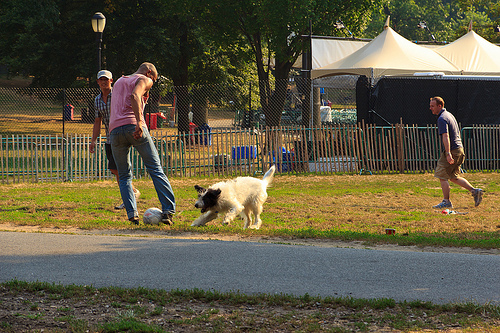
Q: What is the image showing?
A: It is showing a park.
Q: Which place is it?
A: It is a park.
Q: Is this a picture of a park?
A: Yes, it is showing a park.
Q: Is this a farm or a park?
A: It is a park.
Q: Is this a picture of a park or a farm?
A: It is showing a park.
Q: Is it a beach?
A: No, it is a park.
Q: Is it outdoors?
A: Yes, it is outdoors.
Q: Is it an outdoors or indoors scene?
A: It is outdoors.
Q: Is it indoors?
A: No, it is outdoors.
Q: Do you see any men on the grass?
A: Yes, there is a man on the grass.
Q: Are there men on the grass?
A: Yes, there is a man on the grass.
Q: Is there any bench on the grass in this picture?
A: No, there is a man on the grass.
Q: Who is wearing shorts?
A: The man is wearing shorts.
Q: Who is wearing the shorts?
A: The man is wearing shorts.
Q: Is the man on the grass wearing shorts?
A: Yes, the man is wearing shorts.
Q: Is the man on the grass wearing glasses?
A: No, the man is wearing shorts.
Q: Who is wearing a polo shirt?
A: The man is wearing a polo shirt.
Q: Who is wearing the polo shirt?
A: The man is wearing a polo shirt.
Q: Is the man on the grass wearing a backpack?
A: No, the man is wearing a polo shirt.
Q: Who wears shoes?
A: The man wears shoes.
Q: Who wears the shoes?
A: The man wears shoes.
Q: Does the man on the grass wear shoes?
A: Yes, the man wears shoes.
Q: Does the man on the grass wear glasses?
A: No, the man wears shoes.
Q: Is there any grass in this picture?
A: Yes, there is grass.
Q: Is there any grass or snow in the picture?
A: Yes, there is grass.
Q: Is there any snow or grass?
A: Yes, there is grass.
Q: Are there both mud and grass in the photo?
A: No, there is grass but no mud.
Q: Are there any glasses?
A: No, there are no glasses.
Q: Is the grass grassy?
A: Yes, the grass is grassy.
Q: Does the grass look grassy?
A: Yes, the grass is grassy.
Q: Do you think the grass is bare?
A: No, the grass is grassy.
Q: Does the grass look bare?
A: No, the grass is grassy.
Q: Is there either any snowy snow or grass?
A: No, there is grass but it is grassy.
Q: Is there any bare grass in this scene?
A: No, there is grass but it is grassy.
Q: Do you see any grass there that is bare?
A: No, there is grass but it is grassy.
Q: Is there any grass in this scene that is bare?
A: No, there is grass but it is grassy.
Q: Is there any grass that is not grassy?
A: No, there is grass but it is grassy.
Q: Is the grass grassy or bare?
A: The grass is grassy.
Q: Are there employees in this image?
A: No, there are no employees.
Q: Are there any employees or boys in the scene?
A: No, there are no employees or boys.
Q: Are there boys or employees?
A: No, there are no employees or boys.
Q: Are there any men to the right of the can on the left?
A: Yes, there is a man to the right of the can.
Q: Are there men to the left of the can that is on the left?
A: No, the man is to the right of the can.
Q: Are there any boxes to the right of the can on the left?
A: No, there is a man to the right of the can.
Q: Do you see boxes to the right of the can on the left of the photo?
A: No, there is a man to the right of the can.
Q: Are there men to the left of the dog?
A: Yes, there is a man to the left of the dog.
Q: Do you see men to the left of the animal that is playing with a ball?
A: Yes, there is a man to the left of the dog.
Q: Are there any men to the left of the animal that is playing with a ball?
A: Yes, there is a man to the left of the dog.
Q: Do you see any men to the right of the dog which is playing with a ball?
A: No, the man is to the left of the dog.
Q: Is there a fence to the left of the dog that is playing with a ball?
A: No, there is a man to the left of the dog.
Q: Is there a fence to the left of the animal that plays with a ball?
A: No, there is a man to the left of the dog.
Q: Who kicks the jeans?
A: The man kicks the jeans.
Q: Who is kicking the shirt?
A: The man is kicking the shirt.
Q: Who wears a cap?
A: The man wears a cap.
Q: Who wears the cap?
A: The man wears a cap.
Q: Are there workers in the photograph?
A: No, there are no workers.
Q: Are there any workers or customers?
A: No, there are no workers or customers.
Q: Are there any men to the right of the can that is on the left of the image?
A: Yes, there is a man to the right of the can.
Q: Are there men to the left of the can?
A: No, the man is to the right of the can.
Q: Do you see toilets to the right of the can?
A: No, there is a man to the right of the can.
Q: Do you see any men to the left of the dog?
A: Yes, there is a man to the left of the dog.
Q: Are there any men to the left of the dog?
A: Yes, there is a man to the left of the dog.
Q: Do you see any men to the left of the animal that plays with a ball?
A: Yes, there is a man to the left of the dog.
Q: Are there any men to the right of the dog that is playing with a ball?
A: No, the man is to the left of the dog.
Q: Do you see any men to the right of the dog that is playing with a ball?
A: No, the man is to the left of the dog.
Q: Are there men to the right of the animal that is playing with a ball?
A: No, the man is to the left of the dog.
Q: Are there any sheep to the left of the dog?
A: No, there is a man to the left of the dog.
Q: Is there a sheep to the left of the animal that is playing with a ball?
A: No, there is a man to the left of the dog.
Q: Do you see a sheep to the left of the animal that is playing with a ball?
A: No, there is a man to the left of the dog.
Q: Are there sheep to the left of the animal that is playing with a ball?
A: No, there is a man to the left of the dog.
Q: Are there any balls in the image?
A: Yes, there is a ball.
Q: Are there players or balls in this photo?
A: Yes, there is a ball.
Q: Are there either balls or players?
A: Yes, there is a ball.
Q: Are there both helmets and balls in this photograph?
A: No, there is a ball but no helmets.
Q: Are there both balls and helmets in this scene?
A: No, there is a ball but no helmets.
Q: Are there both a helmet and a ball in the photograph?
A: No, there is a ball but no helmets.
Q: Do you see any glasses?
A: No, there are no glasses.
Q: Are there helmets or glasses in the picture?
A: No, there are no glasses or helmets.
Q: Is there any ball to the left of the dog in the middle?
A: Yes, there is a ball to the left of the dog.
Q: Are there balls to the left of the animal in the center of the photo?
A: Yes, there is a ball to the left of the dog.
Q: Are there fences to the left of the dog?
A: No, there is a ball to the left of the dog.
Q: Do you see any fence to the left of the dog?
A: No, there is a ball to the left of the dog.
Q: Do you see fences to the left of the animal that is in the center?
A: No, there is a ball to the left of the dog.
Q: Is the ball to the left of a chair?
A: No, the ball is to the left of a dog.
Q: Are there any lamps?
A: Yes, there is a lamp.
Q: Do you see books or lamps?
A: Yes, there is a lamp.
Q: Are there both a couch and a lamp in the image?
A: No, there is a lamp but no couches.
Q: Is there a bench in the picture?
A: No, there are no benches.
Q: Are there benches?
A: No, there are no benches.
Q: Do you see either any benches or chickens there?
A: No, there are no benches or chickens.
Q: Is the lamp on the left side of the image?
A: Yes, the lamp is on the left of the image.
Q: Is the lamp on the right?
A: No, the lamp is on the left of the image.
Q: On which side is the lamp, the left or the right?
A: The lamp is on the left of the image.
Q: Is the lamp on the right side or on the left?
A: The lamp is on the left of the image.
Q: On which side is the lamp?
A: The lamp is on the left of the image.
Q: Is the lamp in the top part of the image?
A: Yes, the lamp is in the top of the image.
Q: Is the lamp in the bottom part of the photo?
A: No, the lamp is in the top of the image.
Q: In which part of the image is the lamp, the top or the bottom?
A: The lamp is in the top of the image.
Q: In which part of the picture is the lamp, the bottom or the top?
A: The lamp is in the top of the image.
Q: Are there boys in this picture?
A: No, there are no boys.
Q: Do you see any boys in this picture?
A: No, there are no boys.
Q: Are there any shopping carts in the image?
A: No, there are no shopping carts.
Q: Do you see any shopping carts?
A: No, there are no shopping carts.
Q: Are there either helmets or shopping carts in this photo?
A: No, there are no shopping carts or helmets.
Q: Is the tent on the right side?
A: Yes, the tent is on the right of the image.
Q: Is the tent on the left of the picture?
A: No, the tent is on the right of the image.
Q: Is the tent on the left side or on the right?
A: The tent is on the right of the image.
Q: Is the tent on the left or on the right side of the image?
A: The tent is on the right of the image.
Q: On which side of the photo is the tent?
A: The tent is on the right of the image.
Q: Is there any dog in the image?
A: Yes, there is a dog.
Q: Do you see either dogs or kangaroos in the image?
A: Yes, there is a dog.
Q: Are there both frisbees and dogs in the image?
A: No, there is a dog but no frisbees.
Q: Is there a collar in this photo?
A: No, there are no collars.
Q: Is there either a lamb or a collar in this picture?
A: No, there are no collars or lambs.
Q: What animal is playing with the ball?
A: The dog is playing with the ball.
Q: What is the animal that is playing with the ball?
A: The animal is a dog.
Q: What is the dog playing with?
A: The dog is playing with a ball.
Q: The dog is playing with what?
A: The dog is playing with a ball.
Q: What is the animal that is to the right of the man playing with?
A: The dog is playing with a ball.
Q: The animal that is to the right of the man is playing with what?
A: The dog is playing with a ball.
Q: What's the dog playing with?
A: The dog is playing with a ball.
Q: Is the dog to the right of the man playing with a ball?
A: Yes, the dog is playing with a ball.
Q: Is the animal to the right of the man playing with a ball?
A: Yes, the dog is playing with a ball.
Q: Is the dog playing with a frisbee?
A: No, the dog is playing with a ball.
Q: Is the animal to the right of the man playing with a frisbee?
A: No, the dog is playing with a ball.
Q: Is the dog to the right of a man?
A: Yes, the dog is to the right of a man.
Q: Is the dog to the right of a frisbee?
A: No, the dog is to the right of a man.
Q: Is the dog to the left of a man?
A: No, the dog is to the right of a man.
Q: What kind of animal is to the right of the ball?
A: The animal is a dog.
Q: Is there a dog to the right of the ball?
A: Yes, there is a dog to the right of the ball.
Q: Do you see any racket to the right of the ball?
A: No, there is a dog to the right of the ball.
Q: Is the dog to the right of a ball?
A: Yes, the dog is to the right of a ball.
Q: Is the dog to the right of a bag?
A: No, the dog is to the right of a ball.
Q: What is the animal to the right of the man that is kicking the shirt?
A: The animal is a dog.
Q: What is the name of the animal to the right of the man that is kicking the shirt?
A: The animal is a dog.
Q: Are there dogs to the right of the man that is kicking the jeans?
A: Yes, there is a dog to the right of the man.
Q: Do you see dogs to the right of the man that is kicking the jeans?
A: Yes, there is a dog to the right of the man.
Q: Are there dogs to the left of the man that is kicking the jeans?
A: No, the dog is to the right of the man.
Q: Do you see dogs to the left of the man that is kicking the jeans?
A: No, the dog is to the right of the man.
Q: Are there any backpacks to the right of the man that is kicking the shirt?
A: No, there is a dog to the right of the man.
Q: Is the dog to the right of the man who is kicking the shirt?
A: Yes, the dog is to the right of the man.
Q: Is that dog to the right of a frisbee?
A: No, the dog is to the right of the man.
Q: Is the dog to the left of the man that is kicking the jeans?
A: No, the dog is to the right of the man.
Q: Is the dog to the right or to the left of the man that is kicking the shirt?
A: The dog is to the right of the man.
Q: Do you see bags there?
A: No, there are no bags.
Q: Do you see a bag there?
A: No, there are no bags.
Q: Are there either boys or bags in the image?
A: No, there are no bags or boys.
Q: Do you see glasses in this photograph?
A: No, there are no glasses.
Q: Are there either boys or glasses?
A: No, there are no glasses or boys.